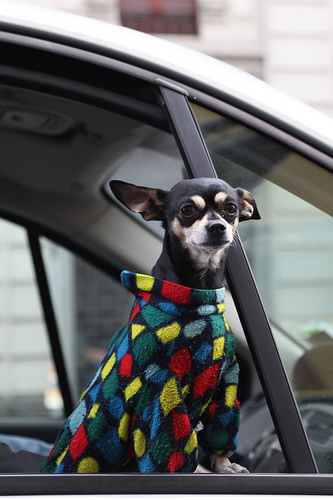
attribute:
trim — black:
[159, 79, 328, 471]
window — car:
[186, 96, 333, 473]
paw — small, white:
[210, 461, 251, 474]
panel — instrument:
[245, 404, 332, 474]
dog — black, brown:
[38, 177, 263, 474]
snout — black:
[193, 209, 231, 249]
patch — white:
[188, 244, 226, 268]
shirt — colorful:
[35, 268, 242, 476]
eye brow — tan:
[187, 195, 206, 207]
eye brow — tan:
[211, 191, 228, 204]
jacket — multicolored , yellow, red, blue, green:
[33, 268, 243, 475]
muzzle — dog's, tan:
[184, 210, 234, 256]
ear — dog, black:
[105, 178, 168, 224]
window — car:
[1, 39, 290, 477]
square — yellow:
[120, 375, 143, 400]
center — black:
[202, 210, 223, 221]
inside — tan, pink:
[239, 199, 253, 215]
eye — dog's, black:
[178, 202, 195, 217]